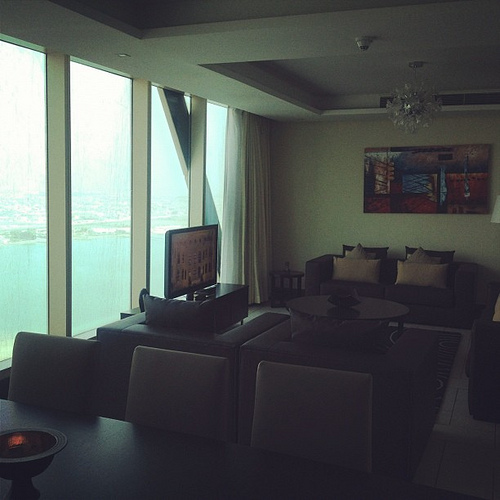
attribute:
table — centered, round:
[290, 294, 408, 329]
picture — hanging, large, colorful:
[363, 145, 491, 216]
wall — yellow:
[270, 119, 499, 290]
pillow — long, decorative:
[337, 257, 377, 280]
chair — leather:
[251, 358, 370, 471]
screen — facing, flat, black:
[164, 225, 216, 297]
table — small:
[171, 282, 247, 329]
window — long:
[70, 61, 132, 336]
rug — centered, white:
[388, 323, 463, 422]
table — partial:
[0, 399, 499, 499]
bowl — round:
[330, 290, 359, 306]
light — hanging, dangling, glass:
[387, 85, 443, 136]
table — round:
[271, 266, 304, 300]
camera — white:
[356, 32, 372, 52]